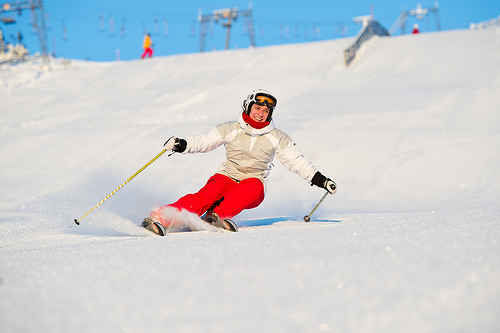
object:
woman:
[140, 91, 334, 234]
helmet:
[242, 88, 276, 126]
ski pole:
[70, 149, 167, 230]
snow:
[0, 24, 496, 331]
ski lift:
[1, 1, 446, 67]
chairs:
[0, 14, 17, 22]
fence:
[342, 12, 389, 65]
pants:
[155, 173, 262, 219]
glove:
[311, 170, 338, 195]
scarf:
[239, 114, 265, 128]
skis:
[140, 217, 176, 239]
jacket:
[183, 122, 314, 182]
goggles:
[249, 93, 274, 106]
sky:
[0, 0, 499, 62]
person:
[142, 33, 151, 59]